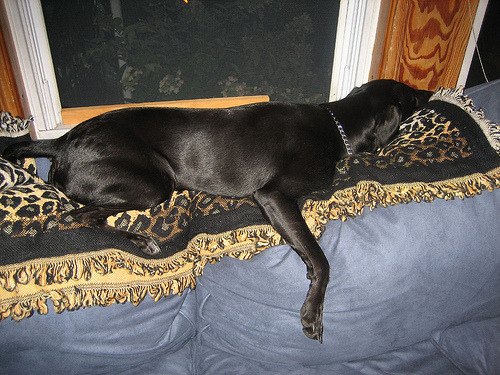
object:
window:
[0, 0, 389, 142]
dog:
[0, 79, 435, 346]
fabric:
[0, 79, 499, 374]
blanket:
[0, 84, 499, 325]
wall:
[375, 0, 488, 93]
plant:
[267, 7, 328, 100]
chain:
[324, 107, 354, 155]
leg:
[107, 157, 175, 209]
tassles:
[419, 190, 441, 202]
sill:
[38, 126, 76, 140]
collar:
[328, 106, 354, 157]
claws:
[316, 336, 323, 346]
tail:
[0, 137, 61, 160]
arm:
[253, 189, 331, 340]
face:
[400, 85, 434, 120]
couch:
[0, 77, 499, 374]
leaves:
[95, 5, 126, 39]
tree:
[228, 1, 279, 85]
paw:
[297, 306, 322, 344]